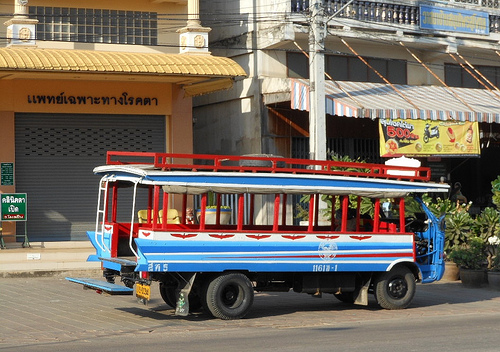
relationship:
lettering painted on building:
[22, 88, 159, 109] [0, 0, 247, 245]